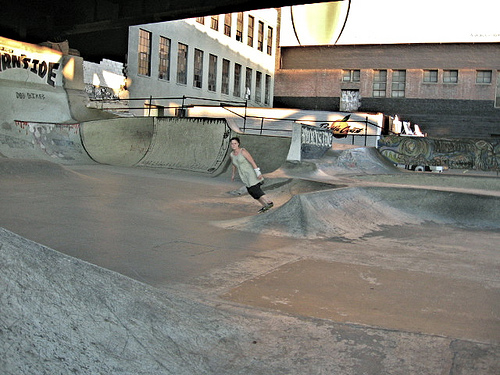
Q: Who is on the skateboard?
A: A girl.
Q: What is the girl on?
A: A skateboard.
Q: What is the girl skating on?
A: A ramp.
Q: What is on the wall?
A: Writing.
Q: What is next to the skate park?
A: A building.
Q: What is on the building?
A: Rows of windows.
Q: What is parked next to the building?
A: A truck.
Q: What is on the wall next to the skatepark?
A: Graffiti.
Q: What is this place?
A: Skate park.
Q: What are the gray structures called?
A: Ramps.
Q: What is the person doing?
A: Skateboarding.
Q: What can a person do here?
A: Practice.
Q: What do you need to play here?
A: Skateboard.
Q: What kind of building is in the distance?
A: Brick.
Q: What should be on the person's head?
A: Helmet.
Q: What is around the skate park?
A: Metal railing.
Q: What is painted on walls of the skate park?
A: Graffiti.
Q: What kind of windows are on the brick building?
A: Glass.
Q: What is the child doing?
A: Skateboarding.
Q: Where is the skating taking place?
A: A skate park.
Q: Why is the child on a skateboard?
A: For exercise.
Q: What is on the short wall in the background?
A: Graffiti.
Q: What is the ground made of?
A: Concrete.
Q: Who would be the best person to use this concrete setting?
A: A skater.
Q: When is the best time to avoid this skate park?
A: When its crowded.